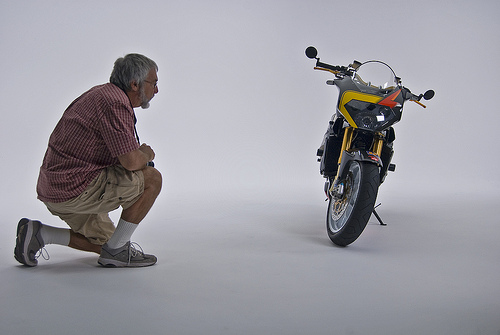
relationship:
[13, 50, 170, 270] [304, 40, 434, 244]
man kneeling next to motorcycle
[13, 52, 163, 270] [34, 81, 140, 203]
man wearing checkered shirt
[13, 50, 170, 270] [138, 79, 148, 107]
man with beard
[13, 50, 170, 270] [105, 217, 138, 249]
man wearing sock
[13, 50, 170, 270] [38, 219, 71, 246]
man wearing sock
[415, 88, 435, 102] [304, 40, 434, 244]
mirror on motorcycle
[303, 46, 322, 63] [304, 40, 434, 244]
mirror on motorcycle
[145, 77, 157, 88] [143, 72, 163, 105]
glasses on face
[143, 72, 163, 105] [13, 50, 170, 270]
face of man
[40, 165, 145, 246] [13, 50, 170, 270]
man's shorts on a man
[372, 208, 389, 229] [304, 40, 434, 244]
kickstand of a motorcycle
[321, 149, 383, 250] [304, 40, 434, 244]
wheel of a motorcycle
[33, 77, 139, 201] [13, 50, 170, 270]
checkered shirt on man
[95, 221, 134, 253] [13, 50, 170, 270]
sock on a man